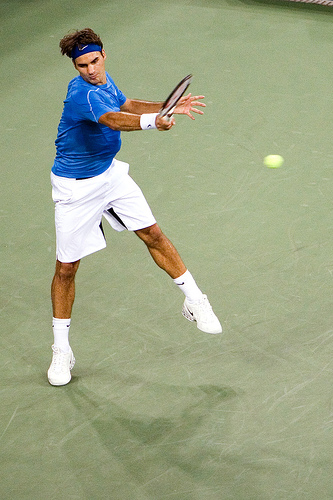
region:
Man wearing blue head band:
[56, 33, 113, 85]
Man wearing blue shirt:
[46, 71, 134, 188]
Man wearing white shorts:
[42, 157, 172, 268]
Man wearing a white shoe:
[31, 308, 91, 405]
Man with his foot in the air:
[111, 205, 248, 374]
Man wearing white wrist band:
[132, 107, 166, 141]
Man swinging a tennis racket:
[142, 61, 209, 142]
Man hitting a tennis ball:
[138, 64, 331, 200]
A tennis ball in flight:
[238, 128, 305, 195]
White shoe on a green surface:
[30, 331, 90, 398]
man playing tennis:
[39, 23, 239, 394]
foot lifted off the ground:
[168, 285, 230, 345]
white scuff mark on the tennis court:
[260, 361, 323, 420]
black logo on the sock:
[172, 278, 188, 289]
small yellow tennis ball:
[260, 150, 284, 171]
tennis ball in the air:
[260, 151, 283, 171]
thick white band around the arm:
[138, 110, 157, 134]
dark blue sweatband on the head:
[65, 42, 106, 62]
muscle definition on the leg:
[143, 240, 185, 279]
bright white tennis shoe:
[41, 343, 84, 388]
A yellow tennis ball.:
[253, 143, 299, 174]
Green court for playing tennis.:
[124, 390, 263, 438]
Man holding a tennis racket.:
[152, 66, 197, 128]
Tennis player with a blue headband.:
[65, 35, 106, 64]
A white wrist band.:
[131, 102, 161, 138]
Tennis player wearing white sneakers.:
[170, 289, 232, 334]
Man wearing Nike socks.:
[154, 260, 205, 311]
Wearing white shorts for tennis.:
[51, 150, 157, 263]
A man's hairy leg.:
[41, 255, 82, 323]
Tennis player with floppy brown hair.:
[52, 24, 101, 57]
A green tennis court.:
[0, 0, 329, 495]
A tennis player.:
[42, 24, 219, 382]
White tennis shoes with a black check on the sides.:
[45, 291, 219, 381]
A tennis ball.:
[263, 152, 279, 164]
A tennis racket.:
[157, 71, 189, 123]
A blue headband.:
[64, 41, 100, 58]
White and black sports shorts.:
[48, 156, 153, 257]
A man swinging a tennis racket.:
[20, 23, 224, 391]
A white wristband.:
[138, 110, 158, 129]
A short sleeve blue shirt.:
[52, 72, 127, 177]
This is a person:
[25, 27, 262, 391]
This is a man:
[43, 20, 251, 409]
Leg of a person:
[42, 195, 111, 435]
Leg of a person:
[113, 170, 241, 366]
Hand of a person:
[109, 77, 218, 116]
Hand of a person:
[78, 85, 175, 146]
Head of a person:
[40, 17, 132, 89]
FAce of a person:
[69, 48, 102, 89]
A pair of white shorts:
[43, 162, 189, 254]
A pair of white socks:
[39, 265, 234, 359]